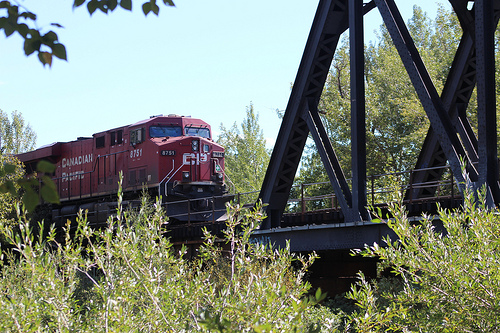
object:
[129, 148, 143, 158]
numbers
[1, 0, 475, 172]
sky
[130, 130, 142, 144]
window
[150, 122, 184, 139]
window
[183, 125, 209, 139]
window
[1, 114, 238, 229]
red train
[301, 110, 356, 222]
steel beam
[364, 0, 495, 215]
steel beam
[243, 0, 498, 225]
crossbeams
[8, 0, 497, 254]
border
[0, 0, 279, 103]
blue sky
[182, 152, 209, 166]
cp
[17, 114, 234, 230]
engine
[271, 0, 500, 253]
bridge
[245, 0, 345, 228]
beam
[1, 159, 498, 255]
bridge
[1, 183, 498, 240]
railing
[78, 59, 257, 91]
clouds